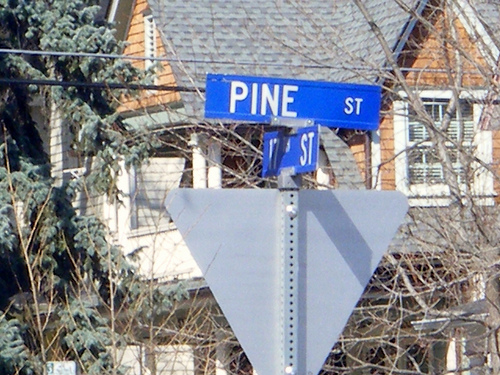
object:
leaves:
[2, 2, 15, 14]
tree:
[2, 0, 165, 374]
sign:
[162, 188, 407, 374]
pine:
[230, 80, 299, 117]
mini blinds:
[407, 101, 474, 181]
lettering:
[227, 80, 362, 117]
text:
[229, 78, 363, 118]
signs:
[202, 73, 382, 131]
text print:
[230, 79, 363, 116]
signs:
[261, 122, 320, 180]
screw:
[284, 204, 302, 218]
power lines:
[0, 49, 500, 75]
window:
[407, 99, 473, 143]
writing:
[228, 81, 362, 117]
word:
[227, 80, 299, 125]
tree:
[95, 0, 500, 374]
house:
[0, 0, 500, 373]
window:
[407, 145, 475, 188]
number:
[269, 133, 283, 169]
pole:
[280, 188, 298, 374]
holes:
[287, 353, 294, 359]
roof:
[130, 0, 422, 124]